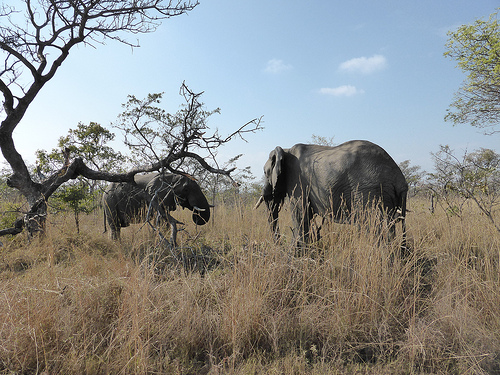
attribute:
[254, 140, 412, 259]
elephant — outdoors, largest, standing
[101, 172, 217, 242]
elephant — outdoors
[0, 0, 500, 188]
clouds — puffy, wispy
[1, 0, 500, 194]
sky — blue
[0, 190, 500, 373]
grass — tall, dry, brown, long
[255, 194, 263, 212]
tusk — white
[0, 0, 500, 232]
trees — thin, green, growing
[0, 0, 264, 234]
branches — bare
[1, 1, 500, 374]
field — wide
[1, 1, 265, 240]
tree — bare, crooked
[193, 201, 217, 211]
tusks — white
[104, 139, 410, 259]
elephants — outdoors